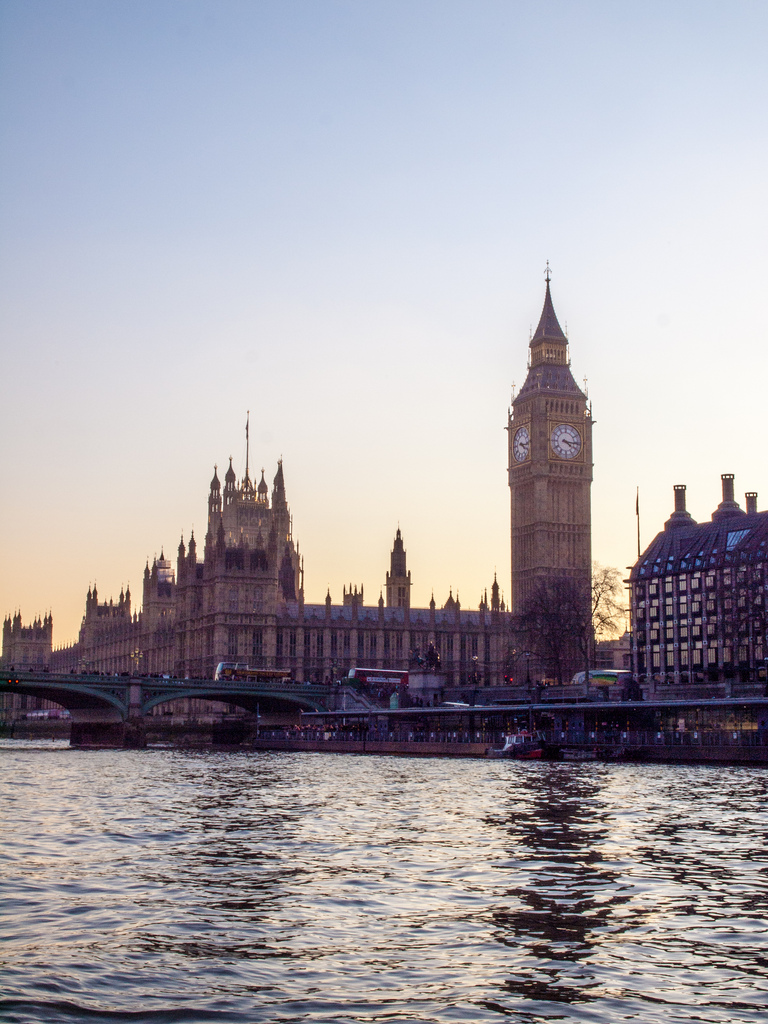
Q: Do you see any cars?
A: No, there are no cars.